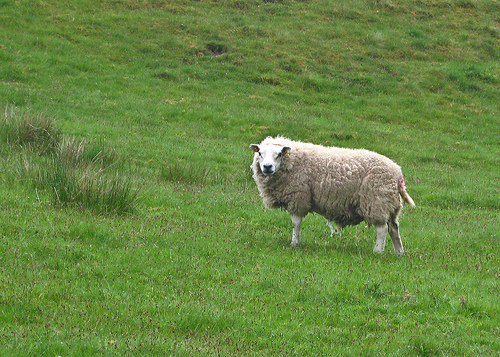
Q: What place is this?
A: It is a field.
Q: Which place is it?
A: It is a field.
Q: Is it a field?
A: Yes, it is a field.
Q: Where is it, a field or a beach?
A: It is a field.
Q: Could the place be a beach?
A: No, it is a field.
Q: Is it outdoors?
A: Yes, it is outdoors.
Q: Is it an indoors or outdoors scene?
A: It is outdoors.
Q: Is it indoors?
A: No, it is outdoors.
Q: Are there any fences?
A: No, there are no fences.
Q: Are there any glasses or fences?
A: No, there are no fences or glasses.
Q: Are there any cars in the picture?
A: No, there are no cars.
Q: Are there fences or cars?
A: No, there are no cars or fences.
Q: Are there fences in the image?
A: No, there are no fences.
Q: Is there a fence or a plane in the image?
A: No, there are no fences or airplanes.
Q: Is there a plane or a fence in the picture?
A: No, there are no fences or airplanes.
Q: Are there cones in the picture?
A: No, there are no cones.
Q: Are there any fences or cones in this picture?
A: No, there are no cones or fences.